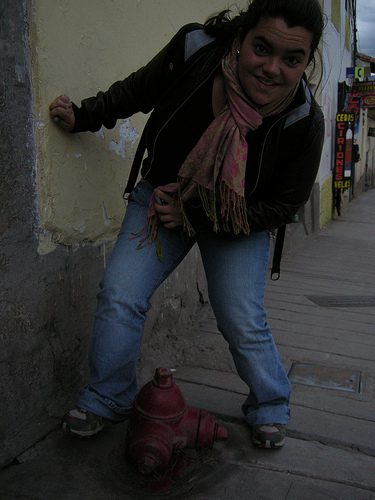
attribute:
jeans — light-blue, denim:
[53, 5, 337, 454]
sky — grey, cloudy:
[354, 0, 373, 60]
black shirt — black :
[69, 19, 331, 249]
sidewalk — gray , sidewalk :
[295, 243, 373, 386]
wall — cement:
[1, 3, 250, 465]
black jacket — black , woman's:
[75, 21, 323, 242]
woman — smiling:
[48, 0, 326, 448]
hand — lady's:
[48, 92, 78, 130]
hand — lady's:
[152, 185, 182, 231]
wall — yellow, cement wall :
[1, 2, 354, 465]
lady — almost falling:
[49, 0, 327, 451]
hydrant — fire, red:
[97, 362, 238, 499]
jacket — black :
[103, 8, 350, 241]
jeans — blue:
[73, 173, 301, 453]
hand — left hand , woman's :
[44, 93, 82, 143]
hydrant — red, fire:
[112, 370, 220, 457]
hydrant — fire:
[123, 363, 222, 462]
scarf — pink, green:
[155, 83, 273, 226]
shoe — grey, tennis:
[251, 423, 287, 451]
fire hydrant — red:
[106, 362, 232, 498]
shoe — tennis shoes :
[244, 413, 291, 453]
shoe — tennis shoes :
[55, 396, 129, 437]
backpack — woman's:
[127, 44, 230, 144]